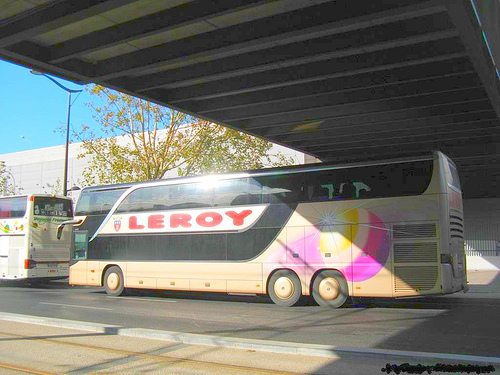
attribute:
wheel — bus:
[308, 272, 345, 309]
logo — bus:
[126, 208, 253, 230]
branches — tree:
[71, 110, 272, 178]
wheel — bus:
[305, 263, 355, 310]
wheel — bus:
[263, 263, 304, 311]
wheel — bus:
[96, 262, 128, 299]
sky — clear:
[6, 93, 60, 135]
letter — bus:
[141, 211, 166, 231]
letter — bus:
[223, 206, 253, 231]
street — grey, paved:
[1, 280, 498, 358]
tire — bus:
[310, 268, 352, 309]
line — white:
[35, 294, 145, 323]